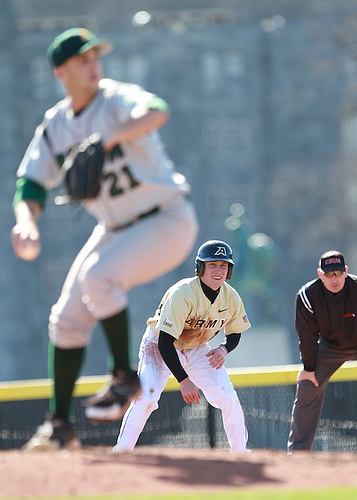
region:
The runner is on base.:
[117, 235, 274, 453]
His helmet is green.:
[190, 231, 238, 278]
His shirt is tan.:
[137, 276, 259, 373]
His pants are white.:
[119, 323, 271, 466]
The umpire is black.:
[269, 224, 354, 456]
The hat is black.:
[309, 238, 343, 286]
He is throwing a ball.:
[18, 132, 137, 449]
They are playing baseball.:
[11, 20, 339, 368]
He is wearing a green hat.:
[38, 17, 99, 77]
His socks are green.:
[39, 305, 148, 408]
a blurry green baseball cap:
[36, 18, 127, 62]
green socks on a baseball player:
[22, 311, 176, 402]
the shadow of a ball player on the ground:
[105, 439, 272, 490]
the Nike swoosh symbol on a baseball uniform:
[216, 301, 230, 314]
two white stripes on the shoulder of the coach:
[295, 285, 319, 313]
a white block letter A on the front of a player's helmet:
[205, 239, 232, 257]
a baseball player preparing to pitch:
[14, 12, 204, 456]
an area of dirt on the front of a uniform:
[175, 312, 214, 351]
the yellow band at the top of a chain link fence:
[241, 363, 285, 392]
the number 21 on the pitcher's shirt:
[84, 163, 145, 196]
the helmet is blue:
[190, 238, 238, 276]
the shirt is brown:
[172, 306, 223, 352]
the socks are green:
[46, 342, 82, 409]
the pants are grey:
[293, 348, 315, 447]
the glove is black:
[63, 141, 125, 199]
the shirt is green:
[19, 180, 40, 203]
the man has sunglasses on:
[301, 265, 356, 460]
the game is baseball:
[4, 188, 347, 496]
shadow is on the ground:
[152, 453, 272, 486]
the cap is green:
[47, 24, 99, 60]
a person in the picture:
[12, 24, 195, 443]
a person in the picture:
[126, 241, 246, 492]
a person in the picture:
[286, 249, 355, 460]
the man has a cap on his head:
[43, 24, 112, 94]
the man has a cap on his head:
[197, 238, 239, 268]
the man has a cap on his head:
[318, 233, 354, 277]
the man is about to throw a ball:
[10, 200, 41, 269]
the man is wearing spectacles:
[321, 264, 351, 280]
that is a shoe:
[81, 370, 141, 425]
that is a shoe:
[30, 420, 78, 460]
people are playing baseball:
[10, 30, 254, 454]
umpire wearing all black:
[280, 251, 356, 452]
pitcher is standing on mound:
[1, 446, 355, 498]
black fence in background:
[0, 362, 356, 459]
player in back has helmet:
[190, 225, 232, 284]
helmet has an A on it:
[214, 245, 226, 257]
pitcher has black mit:
[61, 138, 105, 206]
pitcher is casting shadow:
[79, 445, 281, 494]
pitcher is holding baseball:
[13, 234, 41, 258]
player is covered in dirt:
[175, 323, 213, 354]